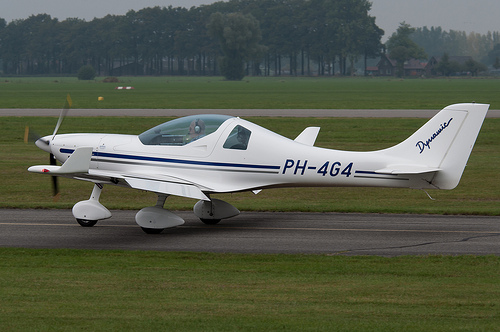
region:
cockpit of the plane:
[139, 112, 228, 147]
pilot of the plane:
[188, 116, 205, 136]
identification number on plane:
[281, 157, 352, 177]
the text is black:
[416, 115, 456, 154]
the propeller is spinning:
[22, 93, 73, 200]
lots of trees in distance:
[1, 0, 498, 77]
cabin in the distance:
[365, 55, 429, 75]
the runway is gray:
[1, 208, 498, 255]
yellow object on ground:
[97, 94, 103, 101]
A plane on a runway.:
[21, 92, 491, 235]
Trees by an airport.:
[1, 0, 498, 80]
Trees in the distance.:
[1, 1, 499, 82]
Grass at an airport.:
[0, 78, 499, 330]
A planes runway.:
[0, 205, 498, 251]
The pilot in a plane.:
[179, 116, 204, 143]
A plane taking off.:
[22, 92, 492, 236]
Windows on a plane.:
[136, 113, 252, 152]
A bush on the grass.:
[74, 61, 96, 81]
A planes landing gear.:
[70, 183, 240, 233]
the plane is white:
[14, 70, 487, 250]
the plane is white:
[28, 72, 488, 229]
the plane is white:
[20, 68, 491, 258]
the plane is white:
[9, 62, 479, 255]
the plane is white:
[9, 64, 486, 269]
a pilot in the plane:
[149, 104, 224, 173]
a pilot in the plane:
[145, 105, 219, 167]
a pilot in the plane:
[136, 107, 237, 185]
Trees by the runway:
[0, 0, 499, 82]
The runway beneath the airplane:
[1, 212, 494, 255]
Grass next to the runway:
[0, 248, 497, 329]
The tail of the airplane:
[375, 102, 492, 189]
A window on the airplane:
[225, 123, 252, 148]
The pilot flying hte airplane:
[183, 117, 205, 144]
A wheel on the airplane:
[76, 213, 95, 226]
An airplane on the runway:
[22, 95, 488, 235]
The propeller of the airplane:
[26, 98, 73, 195]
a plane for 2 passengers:
[26, 80, 488, 235]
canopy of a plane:
[146, 107, 240, 159]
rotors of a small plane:
[14, 80, 84, 207]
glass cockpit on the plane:
[138, 112, 229, 145]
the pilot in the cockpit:
[184, 118, 204, 143]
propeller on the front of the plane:
[47, 95, 73, 194]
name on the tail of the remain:
[416, 115, 453, 152]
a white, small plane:
[25, 95, 491, 230]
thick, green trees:
[0, 0, 499, 77]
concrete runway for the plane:
[0, 205, 497, 252]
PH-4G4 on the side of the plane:
[282, 160, 352, 180]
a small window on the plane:
[222, 124, 249, 148]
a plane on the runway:
[25, 91, 490, 228]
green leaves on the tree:
[288, 26, 319, 43]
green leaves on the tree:
[138, 31, 178, 64]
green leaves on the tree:
[74, 13, 105, 50]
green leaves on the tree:
[182, 23, 205, 50]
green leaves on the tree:
[221, 35, 256, 61]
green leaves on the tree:
[380, 27, 422, 62]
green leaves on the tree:
[42, 34, 94, 63]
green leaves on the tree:
[112, 28, 149, 58]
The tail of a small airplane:
[378, 91, 488, 199]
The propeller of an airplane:
[22, 93, 74, 203]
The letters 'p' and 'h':
[274, 153, 308, 178]